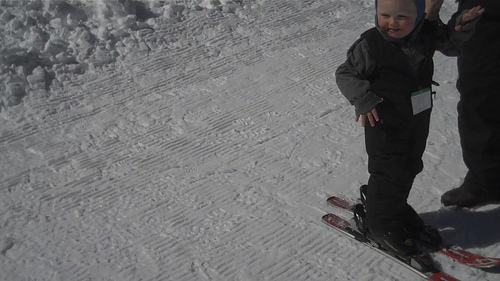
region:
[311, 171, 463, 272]
baby on a set of skis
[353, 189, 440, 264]
baby wearing snow boats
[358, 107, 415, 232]
baby wearing snow pants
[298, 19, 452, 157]
baby wearing snow jackets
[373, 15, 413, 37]
baby with rosy cheeks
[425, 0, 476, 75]
person holding a baby arm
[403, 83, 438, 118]
child with a tag on its jacket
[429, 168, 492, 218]
person wearing brown boats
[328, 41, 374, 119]
baby wearing a gray shirt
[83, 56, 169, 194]
snow on the ground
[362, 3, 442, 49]
face of the boy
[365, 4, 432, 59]
face of the cute boy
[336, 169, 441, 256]
shoes of the boy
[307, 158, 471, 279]
a boy on skatting machine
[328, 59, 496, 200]
two people in snow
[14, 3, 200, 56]
a part of snow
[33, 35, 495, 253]
a beautiful view of snow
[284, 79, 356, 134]
a small line in snow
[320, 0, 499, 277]
A toddler learning to ski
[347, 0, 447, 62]
the head of a baby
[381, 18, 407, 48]
the nose of a baby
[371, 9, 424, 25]
the eyes of a baby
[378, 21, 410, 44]
the mouth of a baby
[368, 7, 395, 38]
the cheek of a baby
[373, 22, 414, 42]
the lips of a baby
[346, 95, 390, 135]
the hand of a baby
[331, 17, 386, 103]
the arm of a baby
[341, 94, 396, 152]
the fingers of a baby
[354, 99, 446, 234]
the legs of a baby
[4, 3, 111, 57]
chunks of snow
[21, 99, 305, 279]
smoothed over snow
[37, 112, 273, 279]
ski tracks in snow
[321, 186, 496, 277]
red skis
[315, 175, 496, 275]
feet strapped to skis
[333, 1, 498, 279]
child standing on skis in snow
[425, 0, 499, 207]
legs of human standing near small child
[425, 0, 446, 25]
wrist of human on child's back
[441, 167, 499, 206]
shoes for standing in snow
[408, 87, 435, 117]
tag for identification